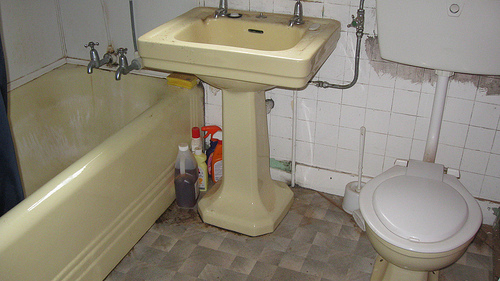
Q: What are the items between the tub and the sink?
A: Cleaning supplies.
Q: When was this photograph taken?
A: The first day of moving in.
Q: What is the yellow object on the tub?
A: Soap.